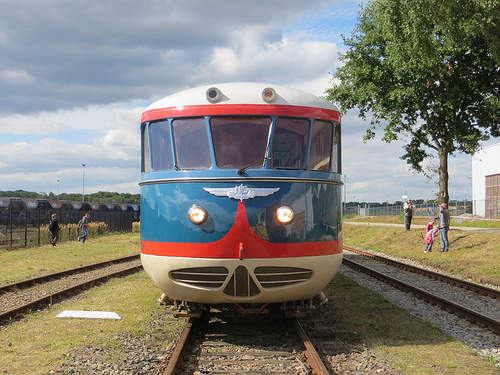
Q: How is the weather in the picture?
A: It is cloudy.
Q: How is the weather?
A: It is cloudy.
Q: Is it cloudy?
A: Yes, it is cloudy.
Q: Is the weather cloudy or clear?
A: It is cloudy.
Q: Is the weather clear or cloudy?
A: It is cloudy.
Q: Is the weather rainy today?
A: No, it is cloudy.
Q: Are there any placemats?
A: No, there are no placemats.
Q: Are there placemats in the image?
A: No, there are no placemats.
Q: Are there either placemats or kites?
A: No, there are no placemats or kites.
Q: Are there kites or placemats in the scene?
A: No, there are no placemats or kites.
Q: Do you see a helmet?
A: No, there are no helmets.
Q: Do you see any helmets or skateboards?
A: No, there are no helmets or skateboards.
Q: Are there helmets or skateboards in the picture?
A: No, there are no helmets or skateboards.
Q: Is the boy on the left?
A: Yes, the boy is on the left of the image.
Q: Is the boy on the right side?
A: No, the boy is on the left of the image.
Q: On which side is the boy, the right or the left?
A: The boy is on the left of the image.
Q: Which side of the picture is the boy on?
A: The boy is on the left of the image.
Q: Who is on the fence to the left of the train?
A: The boy is on the fence.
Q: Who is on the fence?
A: The boy is on the fence.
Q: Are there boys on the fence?
A: Yes, there is a boy on the fence.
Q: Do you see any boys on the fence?
A: Yes, there is a boy on the fence.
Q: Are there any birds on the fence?
A: No, there is a boy on the fence.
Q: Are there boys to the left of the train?
A: Yes, there is a boy to the left of the train.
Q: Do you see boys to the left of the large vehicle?
A: Yes, there is a boy to the left of the train.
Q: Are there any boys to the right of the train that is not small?
A: No, the boy is to the left of the train.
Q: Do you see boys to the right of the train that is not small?
A: No, the boy is to the left of the train.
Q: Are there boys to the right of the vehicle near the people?
A: No, the boy is to the left of the train.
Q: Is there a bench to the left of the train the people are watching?
A: No, there is a boy to the left of the train.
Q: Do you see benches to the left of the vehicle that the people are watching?
A: No, there is a boy to the left of the train.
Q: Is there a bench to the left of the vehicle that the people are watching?
A: No, there is a boy to the left of the train.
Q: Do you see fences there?
A: Yes, there is a fence.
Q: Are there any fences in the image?
A: Yes, there is a fence.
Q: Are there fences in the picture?
A: Yes, there is a fence.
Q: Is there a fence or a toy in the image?
A: Yes, there is a fence.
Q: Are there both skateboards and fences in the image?
A: No, there is a fence but no skateboards.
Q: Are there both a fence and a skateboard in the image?
A: No, there is a fence but no skateboards.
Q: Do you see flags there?
A: No, there are no flags.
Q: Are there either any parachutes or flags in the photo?
A: No, there are no flags or parachutes.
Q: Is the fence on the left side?
A: Yes, the fence is on the left of the image.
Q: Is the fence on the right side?
A: No, the fence is on the left of the image.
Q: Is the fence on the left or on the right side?
A: The fence is on the left of the image.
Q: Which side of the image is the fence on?
A: The fence is on the left of the image.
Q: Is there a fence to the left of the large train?
A: Yes, there is a fence to the left of the train.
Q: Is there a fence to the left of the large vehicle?
A: Yes, there is a fence to the left of the train.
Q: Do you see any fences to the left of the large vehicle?
A: Yes, there is a fence to the left of the train.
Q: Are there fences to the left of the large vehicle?
A: Yes, there is a fence to the left of the train.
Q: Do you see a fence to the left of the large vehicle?
A: Yes, there is a fence to the left of the train.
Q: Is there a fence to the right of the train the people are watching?
A: No, the fence is to the left of the train.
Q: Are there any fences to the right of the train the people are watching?
A: No, the fence is to the left of the train.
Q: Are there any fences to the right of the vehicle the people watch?
A: No, the fence is to the left of the train.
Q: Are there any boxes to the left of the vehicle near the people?
A: No, there is a fence to the left of the train.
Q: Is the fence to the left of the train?
A: Yes, the fence is to the left of the train.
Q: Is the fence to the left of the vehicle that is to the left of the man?
A: Yes, the fence is to the left of the train.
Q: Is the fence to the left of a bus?
A: No, the fence is to the left of the train.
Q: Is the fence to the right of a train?
A: No, the fence is to the left of a train.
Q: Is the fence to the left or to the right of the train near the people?
A: The fence is to the left of the train.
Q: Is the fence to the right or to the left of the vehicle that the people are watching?
A: The fence is to the left of the train.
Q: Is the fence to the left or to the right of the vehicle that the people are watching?
A: The fence is to the left of the train.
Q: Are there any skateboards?
A: No, there are no skateboards.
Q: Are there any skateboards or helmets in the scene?
A: No, there are no skateboards or helmets.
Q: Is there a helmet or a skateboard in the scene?
A: No, there are no skateboards or helmets.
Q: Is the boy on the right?
A: No, the boy is on the left of the image.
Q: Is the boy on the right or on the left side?
A: The boy is on the left of the image.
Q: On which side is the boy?
A: The boy is on the left of the image.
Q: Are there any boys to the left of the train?
A: Yes, there is a boy to the left of the train.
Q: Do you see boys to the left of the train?
A: Yes, there is a boy to the left of the train.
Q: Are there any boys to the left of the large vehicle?
A: Yes, there is a boy to the left of the train.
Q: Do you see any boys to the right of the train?
A: No, the boy is to the left of the train.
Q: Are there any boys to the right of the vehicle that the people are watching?
A: No, the boy is to the left of the train.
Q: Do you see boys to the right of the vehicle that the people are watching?
A: No, the boy is to the left of the train.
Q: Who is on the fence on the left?
A: The boy is on the fence.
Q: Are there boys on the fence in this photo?
A: Yes, there is a boy on the fence.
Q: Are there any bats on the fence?
A: No, there is a boy on the fence.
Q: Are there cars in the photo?
A: No, there are no cars.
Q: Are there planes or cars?
A: No, there are no cars or planes.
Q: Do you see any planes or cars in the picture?
A: No, there are no cars or planes.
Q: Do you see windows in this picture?
A: Yes, there are windows.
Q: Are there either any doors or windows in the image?
A: Yes, there are windows.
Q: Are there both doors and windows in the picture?
A: No, there are windows but no doors.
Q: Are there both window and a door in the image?
A: No, there are windows but no doors.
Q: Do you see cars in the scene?
A: No, there are no cars.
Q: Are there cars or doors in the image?
A: No, there are no cars or doors.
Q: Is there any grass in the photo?
A: Yes, there is grass.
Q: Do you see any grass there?
A: Yes, there is grass.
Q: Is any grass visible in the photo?
A: Yes, there is grass.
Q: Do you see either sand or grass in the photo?
A: Yes, there is grass.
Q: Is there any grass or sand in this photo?
A: Yes, there is grass.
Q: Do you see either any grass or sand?
A: Yes, there is grass.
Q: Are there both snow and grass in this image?
A: No, there is grass but no snow.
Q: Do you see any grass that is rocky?
A: Yes, there is rocky grass.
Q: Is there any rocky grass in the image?
A: Yes, there is rocky grass.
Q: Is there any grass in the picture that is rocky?
A: Yes, there is grass that is rocky.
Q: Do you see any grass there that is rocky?
A: Yes, there is grass that is rocky.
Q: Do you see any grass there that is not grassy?
A: Yes, there is rocky grass.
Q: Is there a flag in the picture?
A: No, there are no flags.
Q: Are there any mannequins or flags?
A: No, there are no flags or mannequins.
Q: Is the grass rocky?
A: Yes, the grass is rocky.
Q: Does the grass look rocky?
A: Yes, the grass is rocky.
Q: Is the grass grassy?
A: No, the grass is rocky.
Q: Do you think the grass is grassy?
A: No, the grass is rocky.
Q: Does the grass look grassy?
A: No, the grass is rocky.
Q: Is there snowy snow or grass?
A: No, there is grass but it is rocky.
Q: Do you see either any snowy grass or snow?
A: No, there is grass but it is rocky.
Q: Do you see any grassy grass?
A: No, there is grass but it is rocky.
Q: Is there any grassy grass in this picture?
A: No, there is grass but it is rocky.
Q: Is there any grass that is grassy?
A: No, there is grass but it is rocky.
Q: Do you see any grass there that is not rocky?
A: No, there is grass but it is rocky.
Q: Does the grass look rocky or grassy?
A: The grass is rocky.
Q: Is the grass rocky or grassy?
A: The grass is rocky.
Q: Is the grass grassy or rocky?
A: The grass is rocky.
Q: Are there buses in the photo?
A: No, there are no buses.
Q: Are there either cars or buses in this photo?
A: No, there are no buses or cars.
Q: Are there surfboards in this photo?
A: No, there are no surfboards.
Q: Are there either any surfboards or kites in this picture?
A: No, there are no surfboards or kites.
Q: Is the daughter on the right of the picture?
A: Yes, the daughter is on the right of the image.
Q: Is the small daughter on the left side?
A: No, the daughter is on the right of the image.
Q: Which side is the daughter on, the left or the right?
A: The daughter is on the right of the image.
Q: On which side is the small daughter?
A: The daughter is on the right of the image.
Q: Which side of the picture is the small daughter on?
A: The daughter is on the right of the image.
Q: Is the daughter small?
A: Yes, the daughter is small.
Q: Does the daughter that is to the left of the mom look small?
A: Yes, the daughter is small.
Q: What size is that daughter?
A: The daughter is small.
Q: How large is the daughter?
A: The daughter is small.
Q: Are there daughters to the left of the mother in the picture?
A: Yes, there is a daughter to the left of the mother.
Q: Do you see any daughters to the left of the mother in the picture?
A: Yes, there is a daughter to the left of the mother.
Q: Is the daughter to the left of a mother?
A: Yes, the daughter is to the left of a mother.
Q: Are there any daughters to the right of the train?
A: Yes, there is a daughter to the right of the train.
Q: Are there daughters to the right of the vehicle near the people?
A: Yes, there is a daughter to the right of the train.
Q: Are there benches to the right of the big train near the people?
A: No, there is a daughter to the right of the train.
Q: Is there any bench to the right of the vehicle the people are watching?
A: No, there is a daughter to the right of the train.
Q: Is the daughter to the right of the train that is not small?
A: Yes, the daughter is to the right of the train.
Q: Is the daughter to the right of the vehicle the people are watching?
A: Yes, the daughter is to the right of the train.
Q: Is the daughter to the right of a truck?
A: No, the daughter is to the right of the train.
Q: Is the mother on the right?
A: Yes, the mother is on the right of the image.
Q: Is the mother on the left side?
A: No, the mother is on the right of the image.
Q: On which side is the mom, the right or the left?
A: The mom is on the right of the image.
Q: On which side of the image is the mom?
A: The mom is on the right of the image.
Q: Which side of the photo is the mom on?
A: The mom is on the right of the image.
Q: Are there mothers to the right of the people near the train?
A: Yes, there is a mother to the right of the people.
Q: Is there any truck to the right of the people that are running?
A: No, there is a mother to the right of the people.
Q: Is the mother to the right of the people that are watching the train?
A: Yes, the mother is to the right of the people.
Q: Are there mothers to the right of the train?
A: Yes, there is a mother to the right of the train.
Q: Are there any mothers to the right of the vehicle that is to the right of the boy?
A: Yes, there is a mother to the right of the train.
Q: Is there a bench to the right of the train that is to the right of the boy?
A: No, there is a mother to the right of the train.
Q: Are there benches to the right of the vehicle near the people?
A: No, there is a mother to the right of the train.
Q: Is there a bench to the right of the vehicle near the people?
A: No, there is a mother to the right of the train.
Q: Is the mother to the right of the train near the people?
A: Yes, the mother is to the right of the train.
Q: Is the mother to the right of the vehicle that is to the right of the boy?
A: Yes, the mother is to the right of the train.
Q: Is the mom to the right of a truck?
A: No, the mom is to the right of the train.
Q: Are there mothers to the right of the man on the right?
A: Yes, there is a mother to the right of the man.